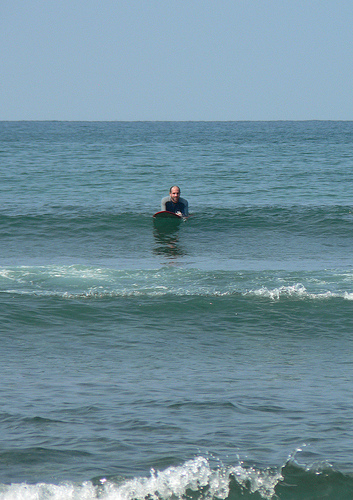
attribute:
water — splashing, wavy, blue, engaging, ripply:
[1, 122, 353, 500]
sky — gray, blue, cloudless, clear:
[1, 1, 352, 122]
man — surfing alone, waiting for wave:
[158, 184, 190, 215]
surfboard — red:
[149, 209, 185, 221]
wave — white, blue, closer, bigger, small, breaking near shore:
[2, 447, 352, 499]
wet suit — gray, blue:
[158, 194, 191, 215]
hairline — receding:
[167, 182, 183, 194]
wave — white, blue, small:
[2, 264, 351, 310]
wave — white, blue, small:
[0, 197, 350, 235]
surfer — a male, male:
[157, 182, 191, 220]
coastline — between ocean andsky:
[0, 117, 353, 128]